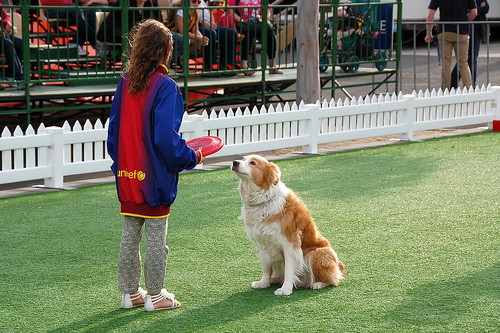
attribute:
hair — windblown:
[125, 16, 173, 93]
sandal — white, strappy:
[142, 285, 182, 310]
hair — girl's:
[118, 11, 172, 98]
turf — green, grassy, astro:
[348, 180, 453, 254]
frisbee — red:
[169, 112, 237, 182]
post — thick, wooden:
[280, 0, 348, 110]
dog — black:
[205, 137, 356, 302]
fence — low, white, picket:
[1, 72, 484, 191]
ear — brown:
[261, 161, 288, 191]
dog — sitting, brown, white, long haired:
[228, 150, 348, 296]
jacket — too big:
[104, 60, 204, 219]